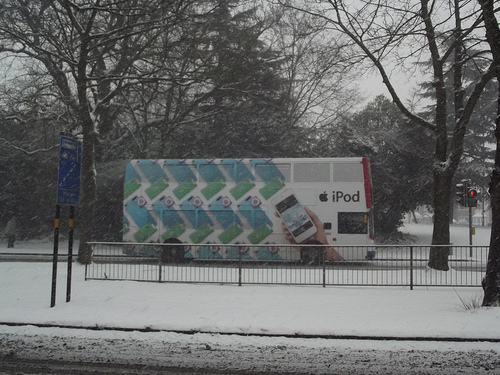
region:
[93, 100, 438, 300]
double-decker bus on road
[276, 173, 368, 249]
iPod advertisement on side of bus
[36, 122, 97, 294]
blue sign beside road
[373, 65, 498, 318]
trees beside the road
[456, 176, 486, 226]
traffic light signaling red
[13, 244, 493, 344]
snow on the ground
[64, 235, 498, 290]
steel railing fence beside road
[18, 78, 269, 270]
snow falling from sky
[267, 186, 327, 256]
hand holding electronic device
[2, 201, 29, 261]
person walking in the snow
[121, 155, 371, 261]
a double decker bus used to advertise the iPod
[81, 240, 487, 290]
a barricade fence marking the sidewalk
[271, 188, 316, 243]
an image of the iPod on the side of the bus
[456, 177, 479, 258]
a traffic light on the corner of the street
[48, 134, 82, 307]
a street sign on the side of the road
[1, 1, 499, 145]
grey gloomy sky means cold and snow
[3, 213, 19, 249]
a person walking on the sidewalk wearing a grey winter jacket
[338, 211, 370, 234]
the side windshield of the driver of the bus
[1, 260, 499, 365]
snow covered road and sidewalk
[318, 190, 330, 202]
the apple logo on the side of the bus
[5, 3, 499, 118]
the grey cloudy sky above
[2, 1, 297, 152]
some tall trees next to the bus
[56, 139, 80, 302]
a sign next to the road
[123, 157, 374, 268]
a double decker bus parked by the corner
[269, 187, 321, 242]
an iPod advertisement on the side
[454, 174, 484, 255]
a traffic light on the side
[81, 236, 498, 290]
a fence next to the road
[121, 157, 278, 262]
more iPods on the bus advertisement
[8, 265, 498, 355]
snow on the sidewalk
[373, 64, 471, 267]
another tree by the bus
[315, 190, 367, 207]
an iPod logo on vehicle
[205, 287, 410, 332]
white snow on ground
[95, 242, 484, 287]
a gate on grass near street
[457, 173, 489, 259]
a red light on traffic struture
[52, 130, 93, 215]
a blue and white sign on grass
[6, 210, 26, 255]
a man walking outdoors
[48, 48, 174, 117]
bare branches on tree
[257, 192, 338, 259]
a cell phone being held on advertisment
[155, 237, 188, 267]
a wheel on the vehicle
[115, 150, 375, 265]
a colorful vehicle on street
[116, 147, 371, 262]
A double-decker bus.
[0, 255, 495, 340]
The ground is covered in snow.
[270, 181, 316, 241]
A picture of an iPod.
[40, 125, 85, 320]
A blue street sign.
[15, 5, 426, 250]
Trees and bushes are behind the bus.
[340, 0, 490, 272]
The tree has lost all of its leaves.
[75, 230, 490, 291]
A metal guardrail.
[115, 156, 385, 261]
The bus has an advertisement on it.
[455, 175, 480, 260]
A stoplight and crosswalk sign.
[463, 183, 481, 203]
The crosswalk sign says don't walk.